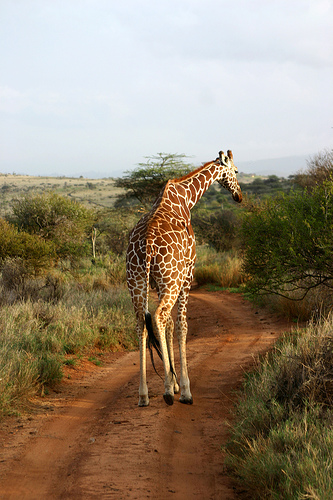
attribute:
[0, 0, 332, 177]
sky — overcast, white, blue, cloudy, in the distance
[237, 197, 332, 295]
tree — bushy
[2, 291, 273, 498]
road — dirt road, brown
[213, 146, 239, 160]
horns — giraffe's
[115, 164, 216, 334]
coat — tan, cream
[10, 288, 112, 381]
grass — bushy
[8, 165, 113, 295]
tree — tallest, in the distance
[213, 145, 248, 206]
head — giraffe's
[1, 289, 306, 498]
road — dirt road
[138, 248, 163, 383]
tail — giraffe's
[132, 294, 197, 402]
legs — giraffe's, tall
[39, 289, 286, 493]
road — dirt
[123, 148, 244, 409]
giraffe — brown, white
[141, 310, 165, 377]
tip — black